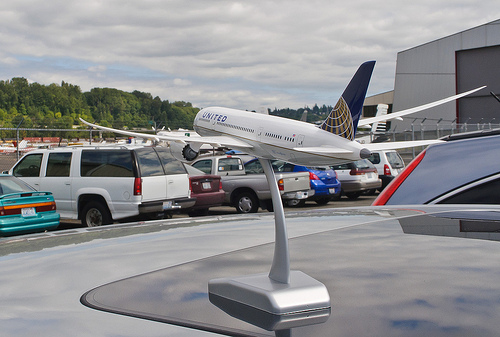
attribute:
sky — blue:
[15, 6, 444, 93]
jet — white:
[181, 72, 384, 170]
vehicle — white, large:
[24, 135, 197, 213]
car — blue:
[261, 159, 361, 196]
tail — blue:
[323, 48, 373, 138]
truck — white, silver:
[193, 152, 311, 202]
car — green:
[5, 169, 63, 238]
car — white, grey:
[51, 199, 495, 333]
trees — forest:
[6, 84, 168, 128]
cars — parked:
[17, 164, 120, 204]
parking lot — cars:
[5, 139, 492, 261]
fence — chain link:
[7, 120, 165, 143]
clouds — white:
[141, 14, 164, 42]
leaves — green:
[30, 109, 43, 119]